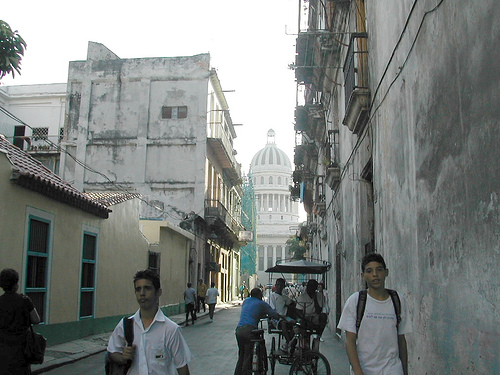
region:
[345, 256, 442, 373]
boy carrying a backpack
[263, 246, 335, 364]
men sitting in back of bicycle transport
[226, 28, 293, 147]
the sky is bright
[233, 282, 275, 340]
man's shirt is blue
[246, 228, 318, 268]
pillars on the building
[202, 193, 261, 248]
balconies on the building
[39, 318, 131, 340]
green along the bottom of the building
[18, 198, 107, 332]
green trim on the windows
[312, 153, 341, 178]
plant on window sill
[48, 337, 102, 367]
sidewalk is cracked and missing pieces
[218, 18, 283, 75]
part of the sky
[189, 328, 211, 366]
part of a floor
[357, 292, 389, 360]
part of a white top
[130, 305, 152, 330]
part of a collar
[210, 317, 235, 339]
part of a floor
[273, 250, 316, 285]
edge of a roof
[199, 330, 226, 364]
part of a floor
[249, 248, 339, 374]
The rickshaw on the street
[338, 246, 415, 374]
The boy with both backpack straps on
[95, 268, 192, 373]
The boy with only one backpack strap on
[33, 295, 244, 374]
The sidewalk next to the yellow and green building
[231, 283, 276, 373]
The man in the blue shirt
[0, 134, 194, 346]
The yellow and green building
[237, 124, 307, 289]
The building with a dome on top of it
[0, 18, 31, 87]
The tree on the left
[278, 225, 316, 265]
The tree shown above the rickshaw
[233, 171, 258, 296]
The green building by the dome building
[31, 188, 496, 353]
two boy in white shirt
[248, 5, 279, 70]
part of the sky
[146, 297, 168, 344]
part of a collar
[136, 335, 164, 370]
part of a shirt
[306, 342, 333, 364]
part of a wheel